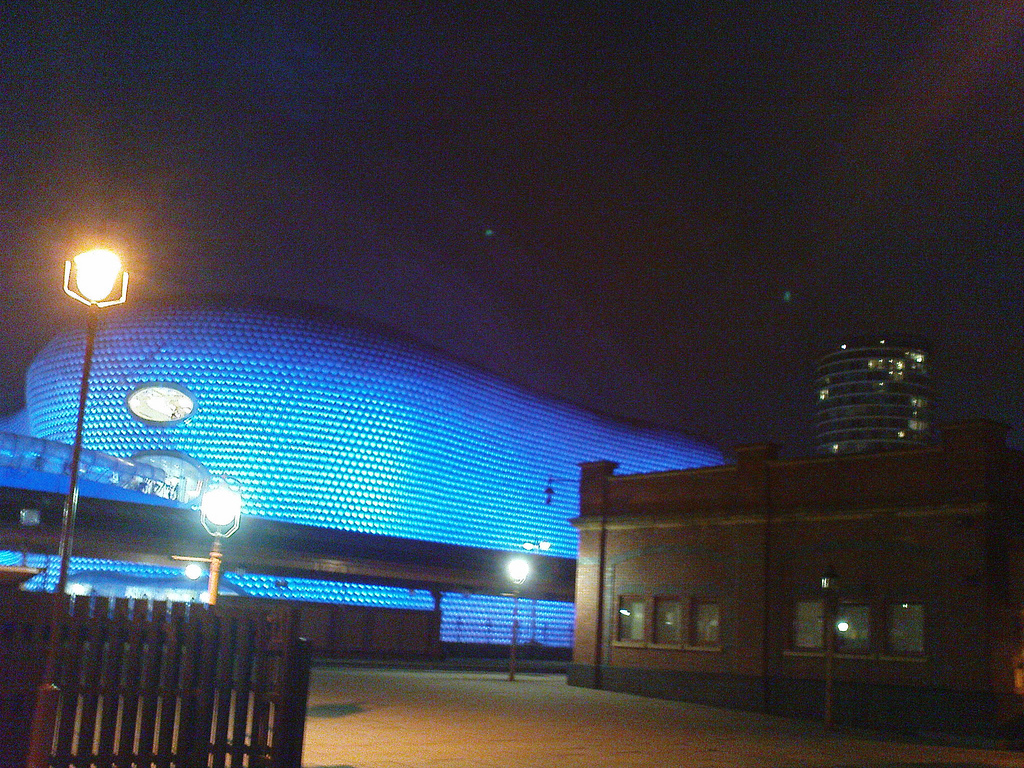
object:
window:
[690, 597, 722, 646]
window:
[791, 599, 826, 651]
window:
[618, 597, 646, 643]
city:
[0, 222, 1024, 767]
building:
[564, 460, 1022, 746]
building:
[0, 305, 731, 667]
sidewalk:
[302, 668, 1022, 768]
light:
[61, 248, 129, 308]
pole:
[39, 315, 115, 591]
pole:
[43, 314, 111, 595]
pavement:
[345, 686, 643, 764]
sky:
[0, 0, 1024, 459]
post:
[200, 545, 228, 598]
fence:
[0, 585, 315, 767]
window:
[652, 597, 683, 645]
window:
[833, 600, 872, 656]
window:
[887, 603, 926, 657]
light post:
[57, 249, 128, 594]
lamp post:
[507, 558, 527, 680]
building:
[810, 331, 949, 457]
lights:
[867, 350, 925, 371]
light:
[202, 489, 241, 526]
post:
[213, 534, 226, 601]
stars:
[485, 230, 792, 302]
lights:
[63, 232, 249, 534]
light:
[128, 386, 194, 421]